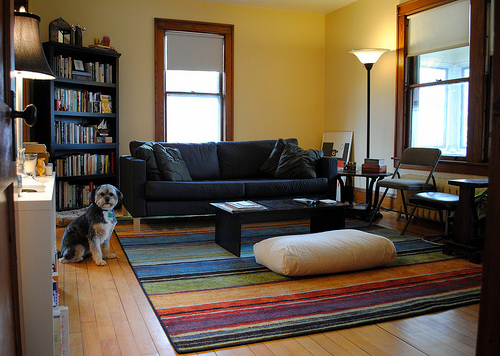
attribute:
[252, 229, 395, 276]
pillow — big, large, white, light colored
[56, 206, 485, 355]
floor — wooden, light brown, hardwood, hardwooden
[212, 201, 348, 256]
center table — black, dark, long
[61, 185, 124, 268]
dog — black, sitting, white, cute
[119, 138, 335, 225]
couch — black, blue, leather, long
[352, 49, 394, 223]
floor lamp — black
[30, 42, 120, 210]
book shelf — black, dark, wooden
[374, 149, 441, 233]
folding chair — gray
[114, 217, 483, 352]
rug — colorful, multi-colored